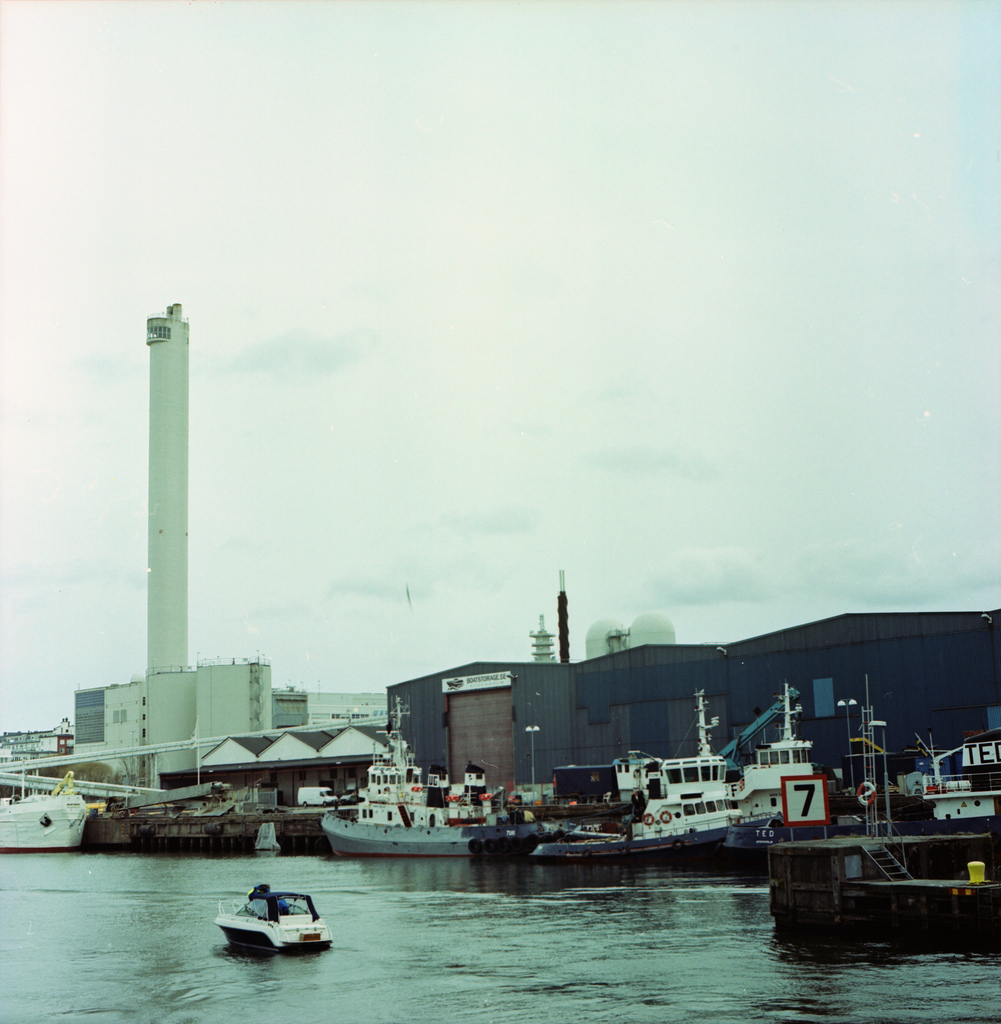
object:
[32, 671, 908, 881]
boats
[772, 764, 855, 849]
sign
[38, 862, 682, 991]
water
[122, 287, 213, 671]
white tower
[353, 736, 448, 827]
white top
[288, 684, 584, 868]
boat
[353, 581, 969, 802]
building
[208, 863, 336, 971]
boat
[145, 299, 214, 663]
cylinder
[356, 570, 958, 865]
building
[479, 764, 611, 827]
door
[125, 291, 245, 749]
tower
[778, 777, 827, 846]
number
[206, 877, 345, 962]
tugboat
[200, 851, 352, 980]
tugboat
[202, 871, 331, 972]
window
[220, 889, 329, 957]
window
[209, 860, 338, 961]
tugboat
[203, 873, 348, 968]
tugboat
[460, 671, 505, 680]
letter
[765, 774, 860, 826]
sign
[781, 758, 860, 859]
sign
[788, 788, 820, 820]
number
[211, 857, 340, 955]
boat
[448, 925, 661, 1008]
water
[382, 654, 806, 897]
building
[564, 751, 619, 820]
door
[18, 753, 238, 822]
stairs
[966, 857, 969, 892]
can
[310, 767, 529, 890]
boat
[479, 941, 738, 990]
water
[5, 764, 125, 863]
van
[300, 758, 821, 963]
ship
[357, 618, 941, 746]
building